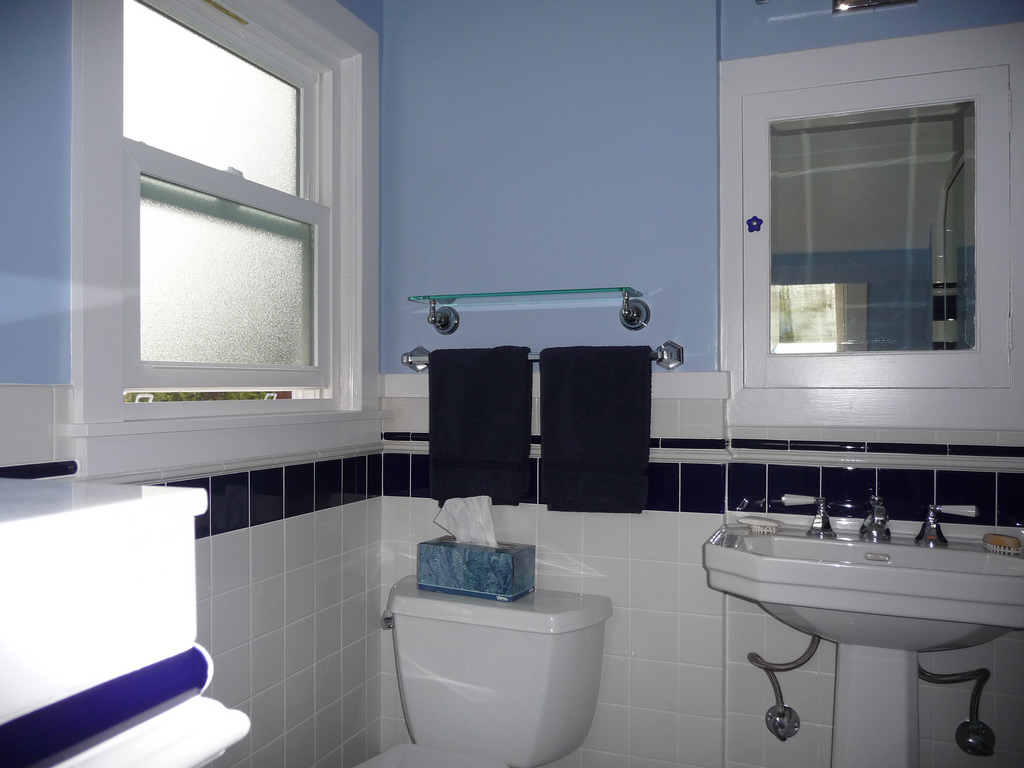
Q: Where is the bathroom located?
A: In the home.